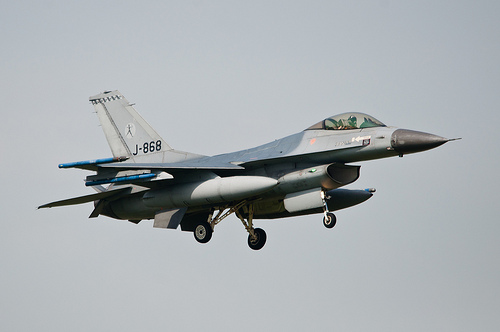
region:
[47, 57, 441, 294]
airplane in the air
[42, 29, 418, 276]
a jet in the air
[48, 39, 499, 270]
airplane flying in the air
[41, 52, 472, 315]
jet flying in the air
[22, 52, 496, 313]
an airplane high in the air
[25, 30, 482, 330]
a jet high in the air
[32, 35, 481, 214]
a gray airplane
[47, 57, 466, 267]
a grey airplane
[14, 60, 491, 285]
a gray jet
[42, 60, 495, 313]
a grey jet in the air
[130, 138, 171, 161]
IDENTIFICATION OF AIRPLANE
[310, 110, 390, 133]
COCKPIT ON MILITARY AIRPLANE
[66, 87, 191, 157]
GREY TAIL OF MILITARY PLANE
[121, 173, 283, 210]
GREY MISSLE ON AIRPLANE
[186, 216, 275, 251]
LANDING GEARS OF AIRPLANE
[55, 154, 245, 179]
BLUE TIPPED AIRPLANE WING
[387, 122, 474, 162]
NOSE TIP OF AIRPLANE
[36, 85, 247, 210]
TAIL AND WING OF MILITARY PLANE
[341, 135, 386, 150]
WRITING ON MILITARY AIRPLANE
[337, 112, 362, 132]
PILOT IN COCKPIT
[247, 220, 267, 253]
small round airplane wheel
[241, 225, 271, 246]
small round airplane wheel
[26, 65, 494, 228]
Jet flying in the sky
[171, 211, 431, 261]
Wheels on bottom of plane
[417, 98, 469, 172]
Point on front of plane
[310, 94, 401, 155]
Window on top of plane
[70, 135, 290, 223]
Wing on side of plane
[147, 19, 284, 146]
Gray sky no clouds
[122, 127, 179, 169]
Number on side of plane tail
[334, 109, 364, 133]
Man piloting the plane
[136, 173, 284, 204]
Missile on side of plane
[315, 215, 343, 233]
Small wheel on front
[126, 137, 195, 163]
Black writing on side of plane.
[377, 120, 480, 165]
Front tip of plane is dark gray.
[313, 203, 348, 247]
Black wheel on plane.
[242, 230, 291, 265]
Black wheel on plane.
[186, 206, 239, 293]
Black wheel on plane.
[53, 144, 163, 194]
Blue weapons on side of plane.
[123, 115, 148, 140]
Circle logon on side of plane.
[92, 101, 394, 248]
Plane is flying in air.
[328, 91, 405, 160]
Clear hatch on front of plane.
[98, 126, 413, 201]
Plane is mostly gray in color.